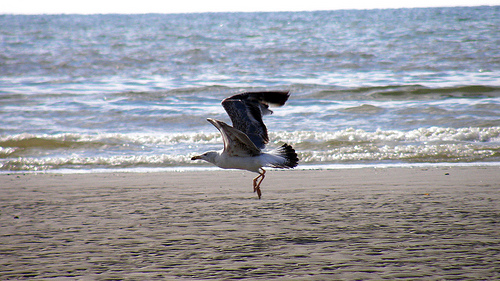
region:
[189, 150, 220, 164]
head of a bird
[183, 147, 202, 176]
peck of a bird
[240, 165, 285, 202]
leg of a bird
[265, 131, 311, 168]
tail of a bird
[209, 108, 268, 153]
wing of a bird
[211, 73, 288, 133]
wing of a bird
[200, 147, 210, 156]
eye of a bird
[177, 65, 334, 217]
bird in mid air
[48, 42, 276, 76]
clear body of water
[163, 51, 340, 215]
a bird near a beach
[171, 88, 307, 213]
bird is trying to fly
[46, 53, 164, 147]
the water is murky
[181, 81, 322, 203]
a seagull flying on a beach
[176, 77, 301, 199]
a seagull over a beach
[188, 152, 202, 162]
the beak of a seagull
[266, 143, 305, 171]
the tail of a seagull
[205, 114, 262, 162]
the wing of a seagull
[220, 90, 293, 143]
the wing of a seagull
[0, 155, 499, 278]
a long strip of beach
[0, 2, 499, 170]
a large body of water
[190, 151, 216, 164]
the head of a seagull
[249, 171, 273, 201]
the feet of a seagull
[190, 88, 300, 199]
Flying sea bird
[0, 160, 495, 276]
Empty sandy beach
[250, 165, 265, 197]
Sea bird's legs extended for landing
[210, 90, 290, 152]
Flapping sea bird wings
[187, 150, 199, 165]
Sea bird beak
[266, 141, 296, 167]
Black and white tail feathers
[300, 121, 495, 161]
White foam on waves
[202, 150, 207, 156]
Dark sea bird eye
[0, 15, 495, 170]
Water with small waves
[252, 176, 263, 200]
Sea bird's webbed feet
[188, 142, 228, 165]
head of a bird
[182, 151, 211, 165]
peck of a bird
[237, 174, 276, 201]
leg of a bird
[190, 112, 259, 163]
wing of a bird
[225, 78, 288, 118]
wing of a bird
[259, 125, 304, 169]
tail of a bird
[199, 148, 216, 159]
eye of a bird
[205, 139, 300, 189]
body of a bird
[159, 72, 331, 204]
bird in mid sky of a bird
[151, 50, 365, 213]
bird near a beach